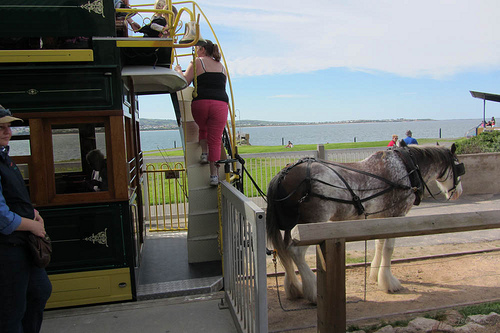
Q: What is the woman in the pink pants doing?
A: Climbing a ladder.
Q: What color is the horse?
A: Brown and white.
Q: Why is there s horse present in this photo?
A: The horse is saddled up and ready to be ridden for profit by children and adults.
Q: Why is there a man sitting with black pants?
A: The man is a professional who is selling rides for the horse within the picture.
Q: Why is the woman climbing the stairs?
A: The woman is climbing the stairs in order to obtain items for the business.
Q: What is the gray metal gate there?
A: The gate opens and closes easily for the elephant.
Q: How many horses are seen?
A: 1.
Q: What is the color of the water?
A: Blue.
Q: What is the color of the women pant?
A: Pink.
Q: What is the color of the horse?
A: White and brown.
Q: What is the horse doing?
A: Standing in ground.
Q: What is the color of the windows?
A: Brown.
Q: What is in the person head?
A: Cap.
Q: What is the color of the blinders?
A: Black.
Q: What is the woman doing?
A: Climbing the stairs.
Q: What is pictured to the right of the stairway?
A: Horse.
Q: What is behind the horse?
A: Metal fence.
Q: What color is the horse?
A: White and brown.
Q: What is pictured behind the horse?
A: A fence.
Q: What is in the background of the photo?
A: A body of water.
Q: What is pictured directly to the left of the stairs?
A: A window.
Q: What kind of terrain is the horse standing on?
A: Sandy.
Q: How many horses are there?
A: One.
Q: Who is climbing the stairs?
A: A woman.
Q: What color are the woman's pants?
A: Pink.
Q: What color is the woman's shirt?
A: Black.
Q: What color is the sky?
A: Blue.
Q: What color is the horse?
A: White and brown.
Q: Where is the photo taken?
A: Outside by the water.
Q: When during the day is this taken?
A: During daylight.